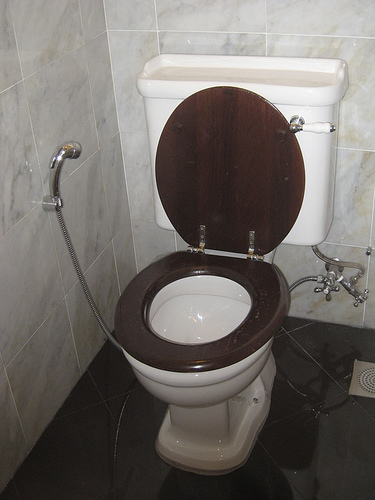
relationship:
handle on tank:
[288, 116, 335, 135] [137, 53, 347, 247]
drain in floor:
[349, 358, 374, 399] [1, 316, 374, 498]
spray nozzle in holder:
[49, 143, 85, 195] [42, 198, 63, 210]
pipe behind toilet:
[289, 270, 324, 291] [121, 338, 279, 477]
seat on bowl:
[114, 251, 291, 372] [121, 338, 279, 477]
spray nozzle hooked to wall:
[49, 143, 85, 195] [0, 2, 374, 491]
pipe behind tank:
[289, 270, 324, 291] [137, 53, 347, 247]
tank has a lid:
[137, 53, 347, 247] [138, 52, 350, 108]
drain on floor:
[349, 358, 374, 399] [1, 316, 374, 498]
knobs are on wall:
[315, 261, 369, 309] [0, 2, 374, 491]